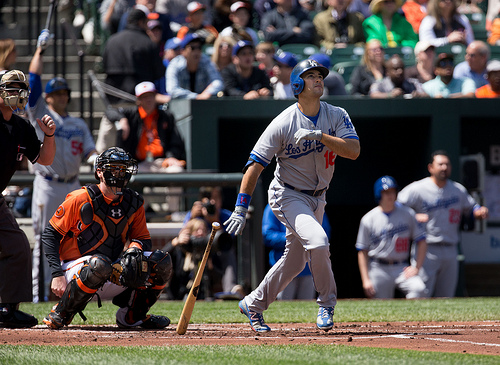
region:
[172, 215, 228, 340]
wooden baseball bat falling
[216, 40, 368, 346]
baseball batter looking up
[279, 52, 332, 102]
blue baseball safety helmet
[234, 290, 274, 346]
aqua blue athletic footwear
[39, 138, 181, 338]
baseball catcher squatted down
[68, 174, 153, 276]
black catcher's safety vest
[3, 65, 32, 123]
silver umpire's safety mask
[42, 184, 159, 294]
orange and black sports shirt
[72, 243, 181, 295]
black and orange knee pads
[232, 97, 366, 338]
gray and blue baseball uniform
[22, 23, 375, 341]
men playing baseball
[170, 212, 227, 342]
a bat color light brown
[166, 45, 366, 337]
baseball player loose a bat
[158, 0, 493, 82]
many viewers in the bleachers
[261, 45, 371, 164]
baseball player looking up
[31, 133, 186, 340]
the catcher wears an orange shirt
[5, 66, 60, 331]
the umpire behind the catcher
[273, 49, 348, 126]
a blue helmet wearing by a baseball player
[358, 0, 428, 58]
woman wearing green cloths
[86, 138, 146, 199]
catcher wears a face protector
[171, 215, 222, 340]
baseball bat falling next to baseball player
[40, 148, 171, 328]
male catcher wearing orange short and mask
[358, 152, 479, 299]
two baseball players watching in the dugout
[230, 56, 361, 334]
baseball player wearing blue and white running after kitting ball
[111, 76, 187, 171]
coach wearing orange in the background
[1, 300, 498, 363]
green and brown baseball field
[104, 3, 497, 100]
crowd of people watching baseball game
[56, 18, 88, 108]
black railing going down steps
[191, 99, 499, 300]
baseball dugout for blue and white team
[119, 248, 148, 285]
black catcher's mitt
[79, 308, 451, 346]
lines outlining batter's box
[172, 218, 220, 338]
leaning wooden baseball bat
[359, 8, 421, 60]
ladies green casual blazer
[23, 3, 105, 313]
baseball player with arm in air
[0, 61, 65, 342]
umpire bracing to make a call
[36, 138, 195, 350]
catcher crouched behind batter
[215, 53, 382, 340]
batter starting to run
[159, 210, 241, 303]
photographer sitting on ground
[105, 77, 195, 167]
man sitting in stand with orange shirt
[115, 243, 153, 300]
black leather catcher's mitt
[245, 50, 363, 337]
Man playing in a baseball game.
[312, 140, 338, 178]
Red number 16 on shirt.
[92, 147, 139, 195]
Face guard on baseball catcher.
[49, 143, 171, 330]
Orange uniform on catcher.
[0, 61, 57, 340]
Umpire in baseball game.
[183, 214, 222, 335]
Wooden baseball bat falling.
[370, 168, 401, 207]
Blue helmet on head.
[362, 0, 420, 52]
Lady is wearing green jacket.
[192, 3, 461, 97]
Crowd watching baseball game.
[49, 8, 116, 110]
Black metal railing on steps.